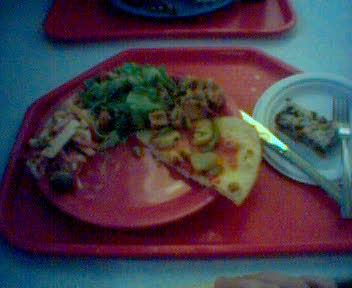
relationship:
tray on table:
[0, 46, 352, 255] [1, 0, 350, 287]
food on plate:
[135, 117, 265, 208] [39, 58, 222, 211]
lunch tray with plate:
[38, 2, 302, 42] [104, 1, 238, 21]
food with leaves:
[135, 117, 265, 208] [76, 59, 176, 149]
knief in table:
[234, 107, 341, 207] [10, 11, 330, 270]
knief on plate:
[219, 88, 347, 183] [49, 34, 340, 249]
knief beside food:
[234, 107, 341, 207] [22, 57, 258, 208]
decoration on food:
[153, 119, 215, 171] [22, 57, 258, 208]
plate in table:
[26, 68, 241, 226] [1, 0, 350, 287]